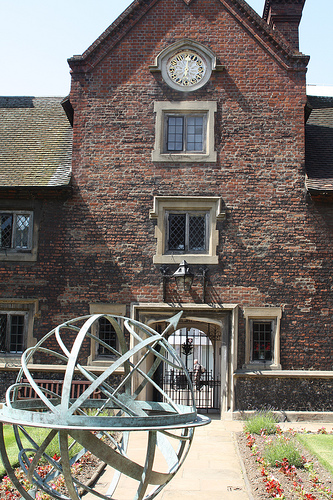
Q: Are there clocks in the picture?
A: Yes, there is a clock.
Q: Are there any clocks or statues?
A: Yes, there is a clock.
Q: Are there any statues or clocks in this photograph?
A: Yes, there is a clock.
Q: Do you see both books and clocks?
A: No, there is a clock but no books.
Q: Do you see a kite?
A: No, there are no kites.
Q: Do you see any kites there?
A: No, there are no kites.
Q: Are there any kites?
A: No, there are no kites.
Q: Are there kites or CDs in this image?
A: No, there are no kites or cds.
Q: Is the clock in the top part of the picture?
A: Yes, the clock is in the top of the image.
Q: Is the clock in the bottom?
A: No, the clock is in the top of the image.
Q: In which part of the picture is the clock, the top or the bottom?
A: The clock is in the top of the image.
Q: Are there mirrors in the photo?
A: No, there are no mirrors.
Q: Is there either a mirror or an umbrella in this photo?
A: No, there are no mirrors or umbrellas.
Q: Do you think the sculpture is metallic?
A: Yes, the sculpture is metallic.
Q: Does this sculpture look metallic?
A: Yes, the sculpture is metallic.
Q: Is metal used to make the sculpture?
A: Yes, the sculpture is made of metal.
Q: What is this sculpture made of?
A: The sculpture is made of metal.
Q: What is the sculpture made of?
A: The sculpture is made of metal.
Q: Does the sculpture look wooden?
A: No, the sculpture is metallic.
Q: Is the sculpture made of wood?
A: No, the sculpture is made of metal.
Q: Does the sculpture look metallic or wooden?
A: The sculpture is metallic.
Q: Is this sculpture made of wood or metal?
A: The sculpture is made of metal.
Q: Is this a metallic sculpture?
A: Yes, this is a metallic sculpture.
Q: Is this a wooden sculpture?
A: No, this is a metallic sculpture.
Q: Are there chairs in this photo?
A: No, there are no chairs.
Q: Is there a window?
A: Yes, there is a window.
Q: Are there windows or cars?
A: Yes, there is a window.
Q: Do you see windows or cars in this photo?
A: Yes, there is a window.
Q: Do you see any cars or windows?
A: Yes, there is a window.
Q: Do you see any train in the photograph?
A: No, there are no trains.